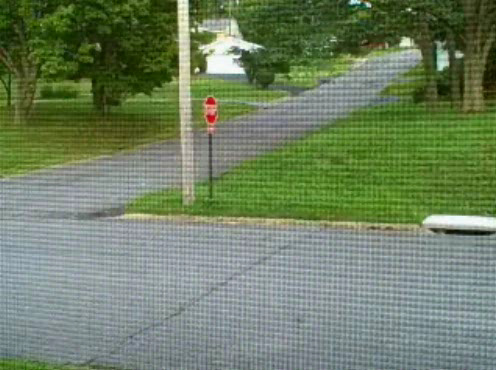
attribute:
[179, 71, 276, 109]
lot — plentiful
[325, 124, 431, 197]
grass — green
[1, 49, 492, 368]
asphalt roads — pictured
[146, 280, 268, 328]
crack — long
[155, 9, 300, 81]
house — white, big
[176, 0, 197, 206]
wooden pole — tall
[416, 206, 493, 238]
thing — white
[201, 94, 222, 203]
sign — stop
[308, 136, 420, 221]
grass — green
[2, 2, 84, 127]
tree — big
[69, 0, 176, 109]
tree — big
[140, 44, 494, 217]
ground — grass-covered